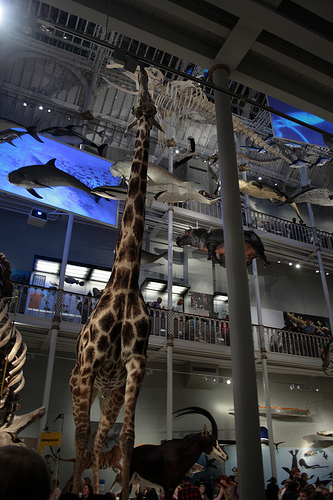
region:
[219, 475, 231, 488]
Woman with red hair looking down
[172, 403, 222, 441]
Curved horns on an animal's head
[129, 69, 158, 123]
Giraffe's head from below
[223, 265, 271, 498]
Tan pillar in a museum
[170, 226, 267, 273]
Hippopotamus hanging from a walkway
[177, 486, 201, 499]
Red and black plaid shirt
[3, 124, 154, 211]
Dolphins hanging from a ceiling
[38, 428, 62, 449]
yellow sign on a wall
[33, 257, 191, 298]
Lights on over a display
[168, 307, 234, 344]
Railing over a walkway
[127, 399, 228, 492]
animal with long horns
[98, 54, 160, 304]
giraffe has long neck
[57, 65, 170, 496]
giraffe is very tall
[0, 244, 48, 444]
animal skeleton on display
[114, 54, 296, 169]
animal skeleton on display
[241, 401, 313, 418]
fish display on wall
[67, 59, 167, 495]
giraffe is brown and tan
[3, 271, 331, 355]
people on balcony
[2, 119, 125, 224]
aquarium on display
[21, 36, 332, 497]
animals on display in museum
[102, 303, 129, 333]
Brown and light brown skin of giraffe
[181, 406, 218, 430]
Horns of the animal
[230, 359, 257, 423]
Small part of large gray pole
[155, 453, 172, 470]
Brown skin of animal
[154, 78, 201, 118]
White bones of an animal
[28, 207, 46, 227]
Black and white camera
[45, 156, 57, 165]
Top fin of fish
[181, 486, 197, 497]
Red and black shirt of man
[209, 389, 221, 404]
White wall on the first floor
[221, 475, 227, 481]
Red hair of the woman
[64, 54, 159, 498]
statute of a giraffe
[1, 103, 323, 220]
several sharks hanging from the ceiling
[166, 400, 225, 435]
horns on one of the animal statutes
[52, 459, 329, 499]
crowd of people looking at the exhibits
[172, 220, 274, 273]
hippo statute hanging from the ceiling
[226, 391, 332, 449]
boats painted onto the wall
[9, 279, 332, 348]
railing on the second floor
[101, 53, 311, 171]
animal skeleton hangin from the ceiling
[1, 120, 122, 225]
fish tank with blue water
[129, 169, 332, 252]
railing on the third floor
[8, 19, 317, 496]
An animal museum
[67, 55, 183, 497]
A large giraffe in a museum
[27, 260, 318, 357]
A balcony in the museum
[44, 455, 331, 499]
People in the museum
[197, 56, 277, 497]
A support beam in the museum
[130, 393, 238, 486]
An animal with horns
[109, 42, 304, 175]
The skeleton of an animal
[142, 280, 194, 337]
People on a balcony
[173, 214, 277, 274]
A hippopotamus in a museum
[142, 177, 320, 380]
Two balconies in a museum